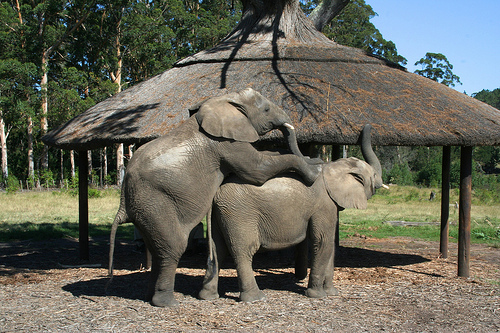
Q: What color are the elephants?
A: Gray.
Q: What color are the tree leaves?
A: Green.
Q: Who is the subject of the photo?
A: The elephants.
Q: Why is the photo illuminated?
A: Sunlight.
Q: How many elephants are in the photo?
A: 2.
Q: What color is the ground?
A: Brown.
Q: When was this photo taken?
A: During the day.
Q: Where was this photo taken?
A: In a zoo.